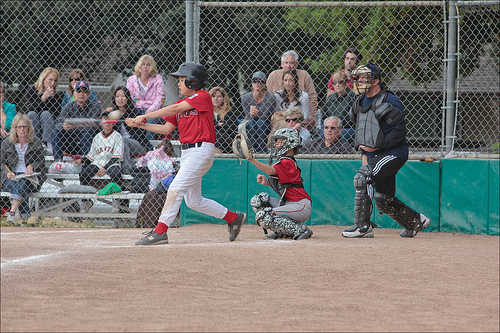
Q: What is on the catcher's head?
A: A mask.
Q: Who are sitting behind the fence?
A: Family and friends.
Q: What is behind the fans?
A: Trees.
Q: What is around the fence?
A: Soft green padding.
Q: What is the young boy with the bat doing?
A: Batting the ball.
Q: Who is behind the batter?
A: Catcher.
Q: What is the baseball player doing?
A: Swinging his bat.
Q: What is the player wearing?
A: Helmet.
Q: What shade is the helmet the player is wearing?
A: Black.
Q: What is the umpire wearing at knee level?
A: Shin guards.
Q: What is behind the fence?
A: Speculators.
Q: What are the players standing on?
A: Dirt.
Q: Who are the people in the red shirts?
A: Boys.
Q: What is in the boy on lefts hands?
A: Baseball bat.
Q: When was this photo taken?
A: Afternoon.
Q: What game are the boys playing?
A: Baseball.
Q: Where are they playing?
A: Baseball field.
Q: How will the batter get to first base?
A: By running.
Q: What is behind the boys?
A: Fence.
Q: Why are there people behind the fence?
A: They are watching.